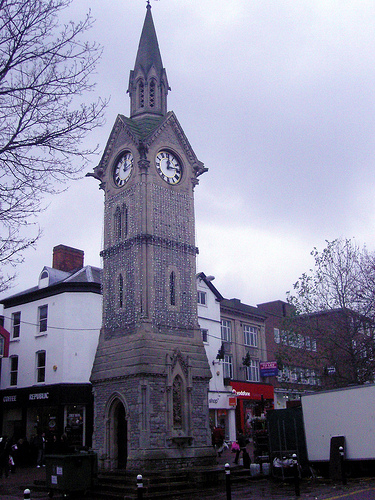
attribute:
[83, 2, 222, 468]
clocktower — grey, tall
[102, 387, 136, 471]
doorway — arched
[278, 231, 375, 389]
tree — small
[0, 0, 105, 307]
branches — bare, tall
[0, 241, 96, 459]
building — white, large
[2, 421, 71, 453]
people — standing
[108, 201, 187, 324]
windows — small, arched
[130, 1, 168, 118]
top — pointed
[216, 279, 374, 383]
buildings — brown, brick, red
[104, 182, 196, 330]
lights — hanging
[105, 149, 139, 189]
clock — white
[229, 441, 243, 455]
bag — pink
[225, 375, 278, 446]
front — red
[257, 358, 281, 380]
sign — mounted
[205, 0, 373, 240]
sky — above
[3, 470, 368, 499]
ground — below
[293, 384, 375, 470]
structure — gray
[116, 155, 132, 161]
numbers — black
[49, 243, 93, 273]
chimney — brick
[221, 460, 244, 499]
pole — metal, black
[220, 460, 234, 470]
tip — white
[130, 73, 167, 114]
window — decorative